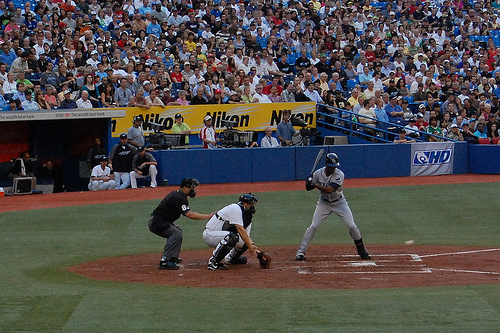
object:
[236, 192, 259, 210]
head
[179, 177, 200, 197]
head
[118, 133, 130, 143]
head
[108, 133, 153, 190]
person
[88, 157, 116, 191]
person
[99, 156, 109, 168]
head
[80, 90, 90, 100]
head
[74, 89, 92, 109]
person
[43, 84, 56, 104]
person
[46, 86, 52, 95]
head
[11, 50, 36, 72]
person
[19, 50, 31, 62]
head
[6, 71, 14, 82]
head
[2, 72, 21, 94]
person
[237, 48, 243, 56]
head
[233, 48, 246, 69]
person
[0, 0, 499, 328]
baseball field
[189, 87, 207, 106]
people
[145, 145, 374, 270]
baseball game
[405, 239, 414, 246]
ball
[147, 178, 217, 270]
human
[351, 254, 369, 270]
dirt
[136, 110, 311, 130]
nikon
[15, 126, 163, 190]
team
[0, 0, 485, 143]
stands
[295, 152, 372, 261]
batter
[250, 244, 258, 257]
hand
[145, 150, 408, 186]
wall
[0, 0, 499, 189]
bleachers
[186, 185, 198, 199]
mask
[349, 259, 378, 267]
home plate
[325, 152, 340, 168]
head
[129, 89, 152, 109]
people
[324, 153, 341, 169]
helmet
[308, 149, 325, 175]
bat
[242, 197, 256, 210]
mask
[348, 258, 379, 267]
plate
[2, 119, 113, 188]
dugout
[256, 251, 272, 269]
glove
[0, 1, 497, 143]
fans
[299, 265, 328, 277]
lines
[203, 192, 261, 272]
catcher